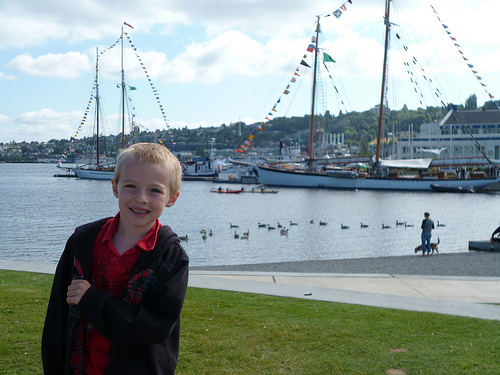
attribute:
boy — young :
[22, 128, 214, 373]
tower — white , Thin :
[225, 112, 250, 157]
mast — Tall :
[369, 2, 397, 182]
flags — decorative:
[249, 14, 484, 174]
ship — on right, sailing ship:
[239, 12, 497, 202]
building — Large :
[397, 105, 498, 162]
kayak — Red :
[209, 183, 253, 199]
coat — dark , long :
[37, 215, 190, 374]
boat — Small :
[430, 183, 477, 199]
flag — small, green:
[321, 50, 336, 69]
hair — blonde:
[113, 141, 183, 208]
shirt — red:
[78, 213, 160, 373]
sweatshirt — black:
[37, 214, 193, 374]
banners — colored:
[46, 25, 418, 132]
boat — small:
[208, 184, 244, 194]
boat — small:
[240, 187, 280, 195]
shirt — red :
[70, 209, 163, 373]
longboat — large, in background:
[250, 151, 483, 191]